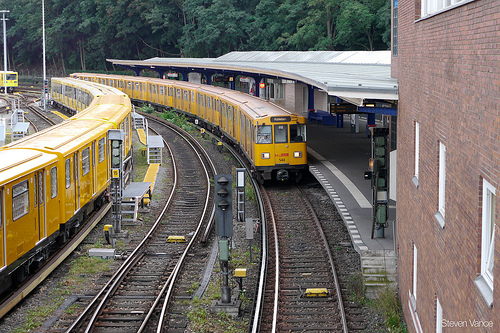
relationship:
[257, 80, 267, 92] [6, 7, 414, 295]
lights on train station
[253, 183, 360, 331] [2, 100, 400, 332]
track on ground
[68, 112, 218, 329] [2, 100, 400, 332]
track on ground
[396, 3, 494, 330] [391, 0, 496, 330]
wall on building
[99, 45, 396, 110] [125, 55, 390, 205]
roof on waiting area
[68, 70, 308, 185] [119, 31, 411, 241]
train at station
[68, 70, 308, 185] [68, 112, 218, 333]
train next to track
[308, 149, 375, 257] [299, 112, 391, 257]
white markings on platform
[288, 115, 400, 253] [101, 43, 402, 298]
platform on station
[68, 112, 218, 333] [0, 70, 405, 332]
track in train yard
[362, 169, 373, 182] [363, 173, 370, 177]
sign with arrow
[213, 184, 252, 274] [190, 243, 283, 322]
arrow on sign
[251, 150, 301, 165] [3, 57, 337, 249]
lights in front of train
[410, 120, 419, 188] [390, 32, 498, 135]
windows on building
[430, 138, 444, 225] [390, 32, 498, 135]
windows on building